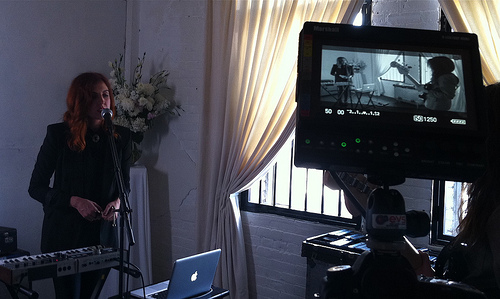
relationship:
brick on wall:
[183, 196, 192, 208] [163, 31, 209, 203]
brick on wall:
[132, 3, 204, 229] [92, 12, 292, 271]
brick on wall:
[256, 221, 301, 240] [136, 2, 443, 297]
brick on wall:
[132, 3, 203, 262] [136, 2, 443, 297]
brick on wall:
[256, 221, 299, 251] [237, 204, 359, 296]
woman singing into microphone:
[24, 69, 158, 267] [96, 107, 117, 136]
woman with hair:
[24, 69, 158, 267] [67, 71, 94, 144]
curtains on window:
[201, 0, 499, 297] [238, 0, 498, 243]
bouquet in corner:
[105, 53, 182, 166] [117, 25, 203, 174]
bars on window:
[258, 137, 341, 216] [238, 1, 450, 243]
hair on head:
[59, 92, 92, 154] [58, 67, 122, 136]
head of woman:
[58, 67, 122, 136] [56, 69, 133, 209]